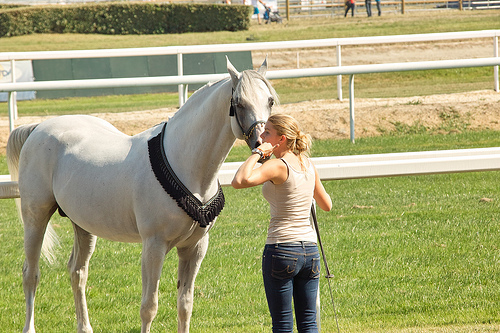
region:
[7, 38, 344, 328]
woman standing with white horse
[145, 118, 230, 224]
black collar around white horse's neck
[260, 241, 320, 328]
blue jeans of woman standing with horse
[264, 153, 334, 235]
tank top of woman standing with horse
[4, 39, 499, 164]
white railings behind white horse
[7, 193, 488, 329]
grass horse and woman are standing on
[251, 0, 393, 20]
people standing in background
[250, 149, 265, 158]
watch on woman's wrist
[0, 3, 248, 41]
shrubbery behind white horse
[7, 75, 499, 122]
dirt path between white railings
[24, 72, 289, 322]
the horse is white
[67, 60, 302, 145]
the horse is white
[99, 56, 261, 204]
the horse is white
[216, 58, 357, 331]
woman standing in front of the horse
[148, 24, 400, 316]
woman standing in front of the horse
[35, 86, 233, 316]
One horse is standing in the grass.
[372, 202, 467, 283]
Grass is green color.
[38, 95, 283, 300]
Horse is white color.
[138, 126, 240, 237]
Color is black color.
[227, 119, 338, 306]
One woman is standing near the horse.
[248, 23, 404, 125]
Rails are white color.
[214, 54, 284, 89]
Two pointed ears for horse.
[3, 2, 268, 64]
Bushes are behind the rail.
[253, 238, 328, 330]
Woman is wearing blue jeans.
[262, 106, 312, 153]
hair is brown color.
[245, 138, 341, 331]
a women standing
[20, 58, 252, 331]
a white horse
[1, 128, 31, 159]
the horse tail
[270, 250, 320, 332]
women wearing blue jeans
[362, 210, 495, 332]
the grass in the field is green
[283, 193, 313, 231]
a tanned blouse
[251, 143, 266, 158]
women is wearing a watch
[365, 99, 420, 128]
dirt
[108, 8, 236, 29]
a green bush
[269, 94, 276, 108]
the left eye of the horse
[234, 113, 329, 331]
lady facing left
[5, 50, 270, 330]
white horse standing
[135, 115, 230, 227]
brown girdle around neck of horse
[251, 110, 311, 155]
lady with blonde hair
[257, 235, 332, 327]
lady wearing blue jeans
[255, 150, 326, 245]
form fitting tank top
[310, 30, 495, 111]
railing around track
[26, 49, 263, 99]
green barricade behind track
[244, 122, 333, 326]
lady holding bridle of horse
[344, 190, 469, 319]
green pasture near horse